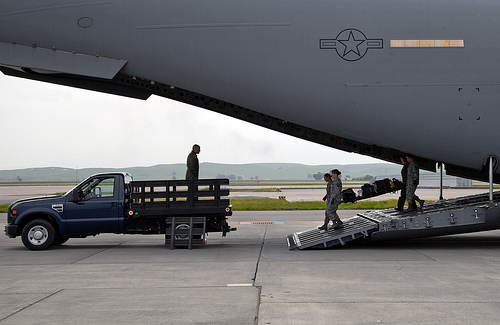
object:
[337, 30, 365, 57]
black star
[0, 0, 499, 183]
plane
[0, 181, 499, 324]
ground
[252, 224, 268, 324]
crack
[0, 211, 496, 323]
runway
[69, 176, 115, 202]
window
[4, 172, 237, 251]
truck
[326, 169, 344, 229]
soldier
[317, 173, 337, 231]
soldier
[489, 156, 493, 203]
pole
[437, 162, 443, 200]
pole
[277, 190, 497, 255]
ramp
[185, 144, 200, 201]
man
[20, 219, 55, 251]
wheel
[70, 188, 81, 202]
mirror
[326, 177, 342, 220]
uniform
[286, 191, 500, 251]
airplane ramp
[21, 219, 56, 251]
front tire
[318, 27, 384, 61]
emblem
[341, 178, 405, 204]
body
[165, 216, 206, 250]
chair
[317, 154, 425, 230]
people